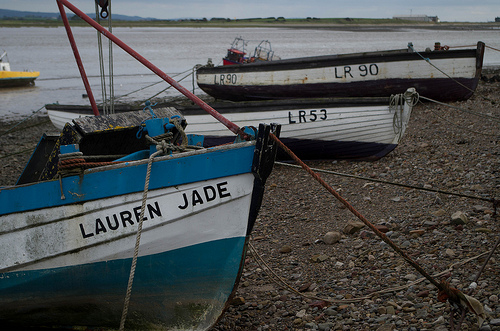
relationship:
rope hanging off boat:
[132, 188, 148, 214] [15, 158, 254, 312]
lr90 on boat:
[319, 60, 393, 84] [204, 62, 487, 97]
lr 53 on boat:
[266, 90, 340, 126] [193, 91, 411, 154]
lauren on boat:
[71, 202, 185, 258] [15, 158, 254, 312]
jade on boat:
[164, 174, 235, 208] [15, 158, 254, 312]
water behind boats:
[138, 29, 203, 51] [108, 44, 415, 222]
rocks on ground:
[465, 98, 485, 111] [289, 227, 352, 274]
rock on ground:
[434, 207, 481, 240] [289, 227, 352, 274]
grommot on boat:
[86, 4, 118, 29] [15, 158, 254, 312]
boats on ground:
[108, 44, 415, 222] [289, 227, 352, 274]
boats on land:
[108, 44, 415, 222] [376, 318, 426, 331]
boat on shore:
[3, 47, 32, 95] [10, 108, 32, 118]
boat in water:
[3, 47, 32, 95] [138, 29, 203, 51]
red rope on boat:
[299, 159, 341, 204] [15, 158, 254, 312]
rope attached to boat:
[132, 188, 148, 214] [15, 158, 254, 312]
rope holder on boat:
[46, 105, 210, 166] [15, 158, 254, 312]